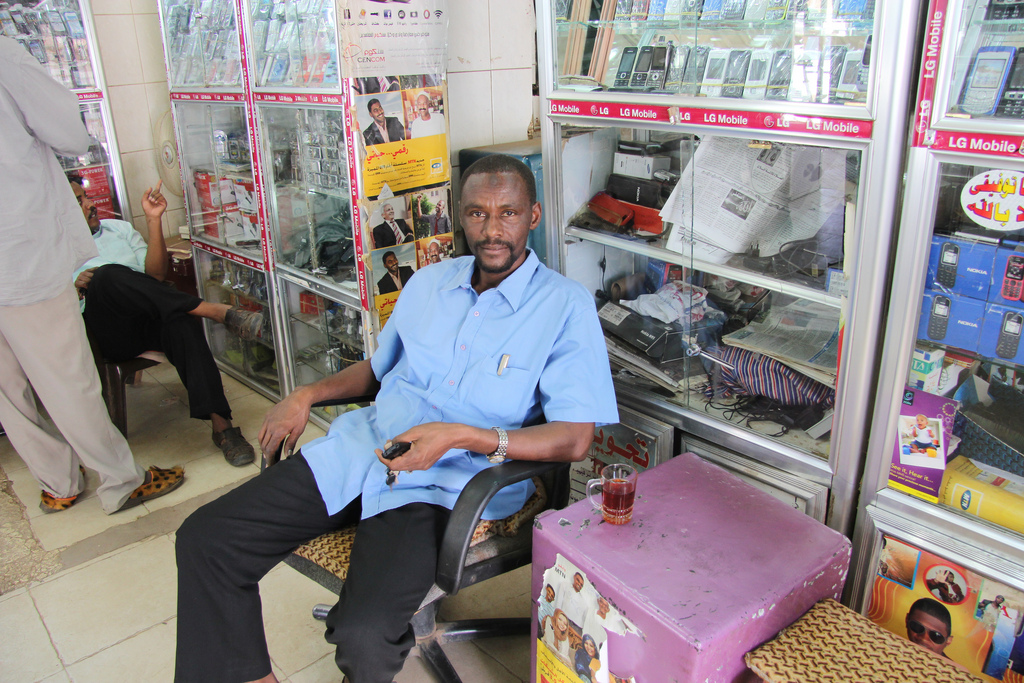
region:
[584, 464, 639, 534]
The glass cup is full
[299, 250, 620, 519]
The button up shirt is blue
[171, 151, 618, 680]
The man is sitting in a chair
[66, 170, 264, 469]
the man is sitting in a chair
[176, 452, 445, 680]
the pants are the color black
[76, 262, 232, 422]
the pants are the color black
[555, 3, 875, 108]
the phones are in a glass case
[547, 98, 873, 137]
the LG sign is pink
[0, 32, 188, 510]
the man suit is gray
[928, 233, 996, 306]
the phone is in a blue box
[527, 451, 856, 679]
a pink colored table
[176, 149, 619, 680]
a man wearing a blue shirt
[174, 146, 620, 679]
a man wearing black pants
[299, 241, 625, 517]
a blue shirt with pens in the pocket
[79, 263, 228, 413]
black colored pants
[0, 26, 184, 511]
a person wearing tan pants and a gray shirt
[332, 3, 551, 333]
papers hanging on a wall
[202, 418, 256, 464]
gray colored shoe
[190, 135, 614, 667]
man sitting in rolling chair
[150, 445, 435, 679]
long black slacks on man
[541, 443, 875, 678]
pink concrete block near man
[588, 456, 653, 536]
glass of liquid near man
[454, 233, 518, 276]
black facial hair on man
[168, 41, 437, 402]
square display cases behind man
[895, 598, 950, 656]
picture of man with sunglasses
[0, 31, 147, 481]
shopper dressed in gray clothes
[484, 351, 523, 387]
pen sticking in man's pocket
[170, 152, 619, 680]
guy sitting in a chair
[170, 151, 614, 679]
guy wearing black dress pants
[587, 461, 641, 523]
glass mug sitting on purple chest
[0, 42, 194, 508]
guy wearing leopard print shoes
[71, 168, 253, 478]
guy sitting with legs crossed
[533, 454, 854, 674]
purple chest sitting near chair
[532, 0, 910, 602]
tall white cabinet full of items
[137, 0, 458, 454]
tall white cabinet covered in plastic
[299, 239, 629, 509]
man wearing a blue shirt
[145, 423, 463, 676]
man wearing black pants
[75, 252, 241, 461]
man wearing black pants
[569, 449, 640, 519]
glass on the table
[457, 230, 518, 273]
man with a goatee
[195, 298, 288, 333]
man wearing black shoes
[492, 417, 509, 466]
man wearing a wrist watch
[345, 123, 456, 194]
poster on the wall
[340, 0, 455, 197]
poster on the wall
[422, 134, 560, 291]
the head of a man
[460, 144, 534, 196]
the hair of a man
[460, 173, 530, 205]
the forehead of a man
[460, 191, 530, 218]
the eyebrows of a man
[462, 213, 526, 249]
the nose of a man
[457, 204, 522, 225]
the eyes of a man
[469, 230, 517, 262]
the mouth of a man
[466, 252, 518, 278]
the chin of a man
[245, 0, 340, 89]
glass window on the building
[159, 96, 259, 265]
glass window on the building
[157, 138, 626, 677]
A man sitting in a chair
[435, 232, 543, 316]
Blue collar of a shirt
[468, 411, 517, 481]
A watch around a wrist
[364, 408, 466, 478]
A black cell phone in a hand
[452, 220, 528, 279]
Facial hair on man's face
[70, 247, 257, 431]
A pair of black pants